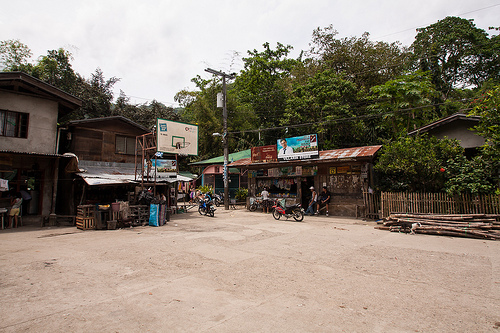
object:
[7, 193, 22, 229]
person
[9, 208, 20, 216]
shorts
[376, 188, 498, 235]
fence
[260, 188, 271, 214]
man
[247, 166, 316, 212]
outdoor market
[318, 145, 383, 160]
metal roof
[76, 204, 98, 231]
crates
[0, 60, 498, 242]
buildings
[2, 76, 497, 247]
stalls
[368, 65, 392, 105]
ground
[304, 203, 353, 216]
bench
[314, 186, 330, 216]
guy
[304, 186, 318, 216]
guy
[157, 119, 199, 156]
white shirt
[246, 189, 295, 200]
counter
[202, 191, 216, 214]
man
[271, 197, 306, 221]
motorcycle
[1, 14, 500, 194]
trees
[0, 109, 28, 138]
window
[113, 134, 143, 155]
window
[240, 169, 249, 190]
window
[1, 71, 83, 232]
building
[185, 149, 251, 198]
building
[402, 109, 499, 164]
building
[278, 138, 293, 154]
person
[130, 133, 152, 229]
hoop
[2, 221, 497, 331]
field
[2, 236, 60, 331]
dirt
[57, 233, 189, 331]
dirt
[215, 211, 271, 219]
dirt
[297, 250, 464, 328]
dirt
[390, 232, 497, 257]
dirt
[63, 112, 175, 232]
building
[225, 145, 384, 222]
building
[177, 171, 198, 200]
building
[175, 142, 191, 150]
basketball hoop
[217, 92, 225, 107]
light fixture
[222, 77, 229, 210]
utility pole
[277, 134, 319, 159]
billboard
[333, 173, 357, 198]
wall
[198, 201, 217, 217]
bicycle